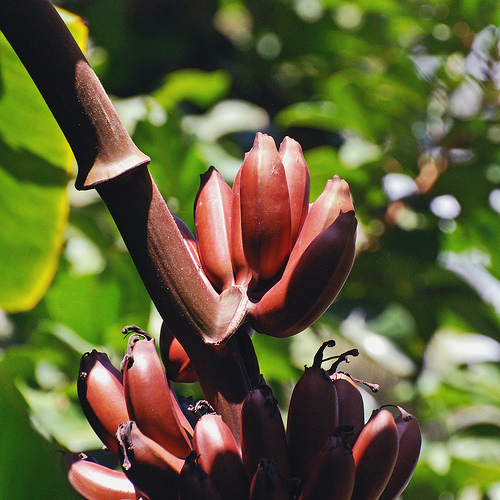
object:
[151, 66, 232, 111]
leaves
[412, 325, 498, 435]
leaves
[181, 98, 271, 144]
leaves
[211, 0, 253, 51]
leaves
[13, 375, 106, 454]
leaves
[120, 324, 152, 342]
stem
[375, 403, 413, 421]
stem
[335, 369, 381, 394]
stem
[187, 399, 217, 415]
stem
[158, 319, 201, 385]
banana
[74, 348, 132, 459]
banana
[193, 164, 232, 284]
banana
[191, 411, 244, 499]
bananas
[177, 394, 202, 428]
fruit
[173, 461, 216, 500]
fruit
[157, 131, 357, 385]
cluster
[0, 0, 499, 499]
ground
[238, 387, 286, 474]
bananas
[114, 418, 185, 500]
bananas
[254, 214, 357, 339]
shadow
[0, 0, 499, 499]
area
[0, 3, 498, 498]
forest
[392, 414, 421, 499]
bananas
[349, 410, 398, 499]
bananas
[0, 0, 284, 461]
branch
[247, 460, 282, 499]
fruit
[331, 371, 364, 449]
bananas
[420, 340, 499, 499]
plant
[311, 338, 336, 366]
flowers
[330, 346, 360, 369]
flowers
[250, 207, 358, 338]
banana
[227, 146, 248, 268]
banana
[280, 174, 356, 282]
banana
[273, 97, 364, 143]
leaves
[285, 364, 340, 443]
bananas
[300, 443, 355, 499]
bananas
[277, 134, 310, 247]
banana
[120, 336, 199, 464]
banana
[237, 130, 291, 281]
banana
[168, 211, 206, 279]
banana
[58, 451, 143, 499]
banana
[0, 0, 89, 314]
leaf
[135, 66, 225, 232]
leaf